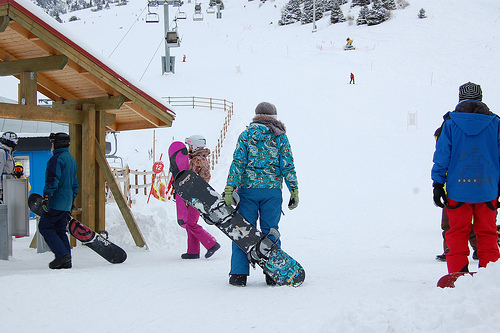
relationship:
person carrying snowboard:
[222, 102, 298, 286] [173, 170, 306, 285]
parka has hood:
[226, 114, 298, 195] [251, 115, 286, 137]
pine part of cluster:
[278, 4, 301, 25] [278, 4, 426, 28]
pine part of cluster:
[302, 4, 322, 24] [278, 4, 426, 28]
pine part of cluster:
[332, 6, 345, 24] [278, 4, 426, 28]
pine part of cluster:
[363, 7, 388, 25] [278, 4, 426, 28]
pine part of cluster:
[416, 6, 426, 19] [278, 4, 426, 28]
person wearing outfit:
[222, 102, 298, 286] [226, 116, 298, 276]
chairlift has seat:
[106, 3, 227, 83] [163, 31, 179, 45]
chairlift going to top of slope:
[106, 3, 227, 83] [8, 6, 494, 327]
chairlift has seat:
[106, 3, 227, 83] [144, 12, 160, 25]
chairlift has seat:
[106, 3, 227, 83] [174, 10, 188, 21]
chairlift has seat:
[106, 3, 227, 83] [191, 9, 205, 22]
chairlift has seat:
[106, 3, 227, 83] [105, 127, 125, 187]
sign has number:
[145, 152, 165, 205] [151, 161, 163, 173]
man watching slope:
[432, 83, 498, 288] [8, 6, 494, 327]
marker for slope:
[405, 109, 418, 129] [8, 6, 494, 327]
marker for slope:
[233, 61, 243, 77] [8, 6, 494, 327]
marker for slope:
[312, 40, 325, 52] [8, 6, 494, 327]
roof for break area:
[3, 7, 175, 133] [3, 120, 174, 271]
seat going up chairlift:
[163, 31, 179, 45] [106, 3, 227, 83]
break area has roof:
[3, 120, 174, 271] [3, 7, 175, 133]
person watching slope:
[222, 102, 298, 286] [8, 6, 494, 327]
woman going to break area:
[181, 133, 221, 259] [3, 120, 174, 271]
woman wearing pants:
[181, 133, 221, 259] [182, 201, 218, 253]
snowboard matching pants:
[169, 141, 190, 227] [182, 201, 218, 253]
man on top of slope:
[347, 69, 356, 86] [8, 6, 494, 327]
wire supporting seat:
[135, 2, 184, 93] [163, 31, 179, 45]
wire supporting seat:
[135, 2, 184, 93] [174, 10, 188, 21]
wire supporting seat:
[135, 2, 184, 93] [191, 9, 205, 22]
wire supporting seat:
[102, 4, 150, 66] [144, 12, 160, 25]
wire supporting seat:
[135, 2, 184, 93] [105, 127, 125, 187]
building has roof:
[3, 133, 54, 220] [3, 136, 111, 153]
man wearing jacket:
[432, 83, 498, 288] [431, 101, 497, 203]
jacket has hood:
[431, 101, 497, 203] [450, 110, 496, 137]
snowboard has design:
[173, 170, 306, 285] [266, 244, 302, 285]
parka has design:
[226, 114, 298, 195] [229, 125, 297, 189]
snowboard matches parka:
[173, 170, 306, 285] [226, 114, 298, 195]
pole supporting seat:
[162, 0, 175, 74] [105, 127, 125, 187]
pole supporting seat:
[162, 0, 175, 74] [163, 31, 179, 45]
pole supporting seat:
[162, 0, 175, 74] [144, 12, 160, 25]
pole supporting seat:
[162, 0, 175, 74] [174, 10, 188, 21]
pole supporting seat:
[162, 0, 175, 74] [191, 9, 205, 22]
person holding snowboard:
[222, 102, 298, 286] [173, 170, 306, 285]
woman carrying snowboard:
[181, 133, 221, 259] [169, 141, 190, 227]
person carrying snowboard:
[38, 132, 79, 268] [28, 192, 127, 264]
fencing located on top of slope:
[106, 95, 235, 198] [8, 6, 494, 327]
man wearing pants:
[432, 83, 498, 288] [444, 194, 498, 276]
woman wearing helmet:
[181, 133, 221, 259] [186, 134, 206, 151]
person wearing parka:
[222, 102, 298, 286] [226, 114, 298, 195]